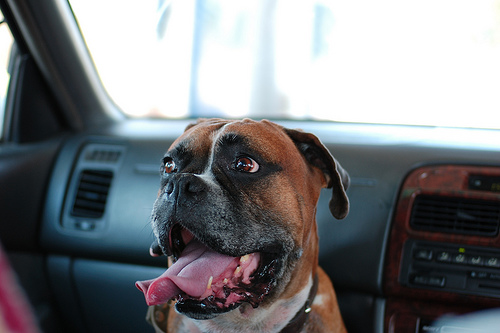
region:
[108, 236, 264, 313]
the dog`s tongue is pink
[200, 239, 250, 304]
the dog`s teeth are yellow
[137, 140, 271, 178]
the dog`s eyes are reddish brown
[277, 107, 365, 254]
the dog has floppy ears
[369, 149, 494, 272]
the car has wood grain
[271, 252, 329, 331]
the dog is wearing a collar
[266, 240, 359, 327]
the collar is brown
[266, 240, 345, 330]
the collar is leather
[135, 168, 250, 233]
the dog has a black nose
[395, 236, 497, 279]
the symbols are white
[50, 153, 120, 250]
air vent in a car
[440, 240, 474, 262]
green light on radio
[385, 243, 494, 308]
black radio in a car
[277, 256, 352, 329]
brown collar on a dog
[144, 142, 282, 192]
brown eyes of a dog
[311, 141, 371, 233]
floppy ear of a dog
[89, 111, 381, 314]
a dog in a car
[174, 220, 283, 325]
tongue of a dog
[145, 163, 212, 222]
black nose of a dog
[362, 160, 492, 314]
brown wooden design panel on car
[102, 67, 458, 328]
a dog with its tongue out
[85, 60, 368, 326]
a dog with floppy ears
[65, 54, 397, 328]
a brown and black dog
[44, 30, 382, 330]
a dog inside a car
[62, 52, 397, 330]
a dog sitting in a car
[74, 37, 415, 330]
a car with a dog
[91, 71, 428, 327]
a car with a panting dog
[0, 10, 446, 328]
a brown and black dog in a car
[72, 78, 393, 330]
a black and brown dog sitting down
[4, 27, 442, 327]
a black and brown dog with tongue out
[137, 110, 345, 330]
a large dog's face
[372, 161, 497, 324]
a vehicle center console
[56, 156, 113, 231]
a vehicle air vent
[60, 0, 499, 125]
a vehicle front windshield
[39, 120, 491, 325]
a vehicle dashboard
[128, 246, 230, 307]
a dog's pink tongue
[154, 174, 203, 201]
a dog's black nose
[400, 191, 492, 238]
a vehicle's air vent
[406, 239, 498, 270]
set of climate control buttons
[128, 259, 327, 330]
a dog's black collar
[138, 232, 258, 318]
long pink dog tongue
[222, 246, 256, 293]
pink gums and white teeth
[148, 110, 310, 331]
brown and black dog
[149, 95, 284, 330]
dog inside a car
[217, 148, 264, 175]
brown eyes of dog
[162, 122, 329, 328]
black and brown dog looking to the left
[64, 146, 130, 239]
black interior of a car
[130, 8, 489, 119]
light shining in through windshield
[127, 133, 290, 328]
dog with tongue out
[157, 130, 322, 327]
dog with mouth open